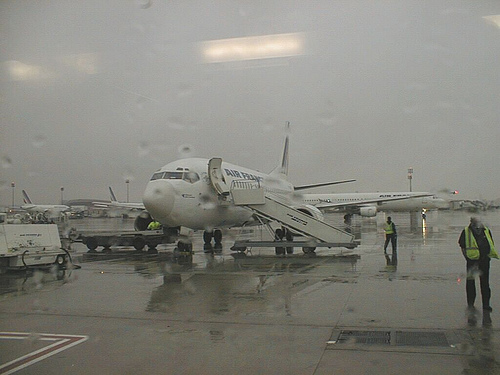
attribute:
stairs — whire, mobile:
[222, 180, 359, 253]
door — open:
[210, 157, 231, 197]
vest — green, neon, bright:
[461, 225, 497, 258]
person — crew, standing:
[456, 210, 497, 312]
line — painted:
[2, 330, 91, 371]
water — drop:
[171, 142, 193, 157]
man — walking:
[377, 215, 401, 263]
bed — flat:
[71, 226, 165, 239]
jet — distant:
[18, 189, 72, 217]